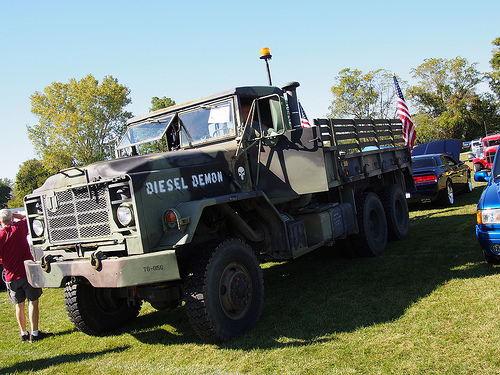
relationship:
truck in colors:
[33, 85, 410, 293] [135, 154, 189, 166]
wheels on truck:
[353, 184, 413, 255] [33, 85, 410, 293]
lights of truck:
[113, 206, 136, 226] [33, 85, 410, 293]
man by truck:
[1, 204, 45, 329] [33, 85, 410, 293]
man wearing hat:
[1, 204, 45, 329] [1, 207, 10, 217]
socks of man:
[31, 328, 39, 336] [1, 204, 45, 329]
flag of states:
[390, 72, 417, 150] [390, 72, 419, 153]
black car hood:
[432, 142, 440, 151] [411, 140, 460, 161]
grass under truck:
[363, 266, 415, 318] [33, 85, 410, 293]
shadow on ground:
[310, 263, 394, 327] [324, 290, 470, 372]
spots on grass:
[370, 332, 392, 349] [363, 266, 415, 318]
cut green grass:
[352, 318, 411, 372] [363, 266, 415, 318]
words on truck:
[143, 169, 227, 192] [33, 85, 410, 293]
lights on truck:
[113, 206, 136, 226] [33, 85, 410, 293]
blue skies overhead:
[84, 16, 106, 28] [6, 3, 168, 46]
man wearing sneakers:
[1, 204, 45, 329] [20, 330, 55, 345]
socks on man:
[31, 328, 39, 336] [1, 204, 45, 329]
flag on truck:
[390, 72, 417, 150] [33, 85, 410, 293]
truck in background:
[33, 85, 410, 293] [11, 22, 498, 168]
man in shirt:
[1, 204, 45, 329] [1, 227, 31, 278]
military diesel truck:
[155, 149, 209, 167] [33, 85, 410, 293]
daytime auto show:
[12, 7, 145, 59] [403, 122, 499, 268]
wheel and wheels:
[179, 237, 270, 336] [353, 193, 389, 255]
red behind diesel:
[488, 135, 495, 156] [394, 132, 477, 213]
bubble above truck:
[257, 43, 272, 61] [33, 85, 410, 293]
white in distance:
[472, 142, 476, 152] [460, 136, 487, 161]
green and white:
[145, 201, 159, 232] [472, 142, 476, 152]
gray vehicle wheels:
[223, 298, 232, 311] [353, 193, 389, 255]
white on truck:
[472, 142, 476, 152] [20, 85, 413, 346]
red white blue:
[488, 135, 495, 156] [84, 16, 106, 28]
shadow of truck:
[310, 263, 394, 327] [20, 85, 413, 346]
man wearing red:
[1, 204, 45, 329] [488, 135, 495, 156]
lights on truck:
[113, 206, 136, 226] [20, 85, 413, 346]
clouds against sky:
[147, 53, 207, 84] [6, 7, 248, 69]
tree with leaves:
[27, 75, 127, 148] [104, 83, 121, 100]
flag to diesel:
[390, 72, 417, 150] [394, 138, 472, 211]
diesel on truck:
[394, 132, 477, 213] [33, 85, 410, 293]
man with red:
[1, 204, 45, 329] [488, 135, 495, 156]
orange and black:
[260, 49, 266, 55] [432, 142, 440, 151]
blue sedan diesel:
[84, 16, 106, 28] [394, 138, 472, 211]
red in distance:
[488, 135, 495, 156] [460, 136, 487, 161]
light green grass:
[471, 317, 491, 339] [363, 266, 415, 318]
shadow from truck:
[310, 263, 394, 327] [33, 85, 410, 293]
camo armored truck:
[195, 148, 240, 172] [33, 85, 410, 293]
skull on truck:
[234, 161, 246, 185] [33, 85, 410, 293]